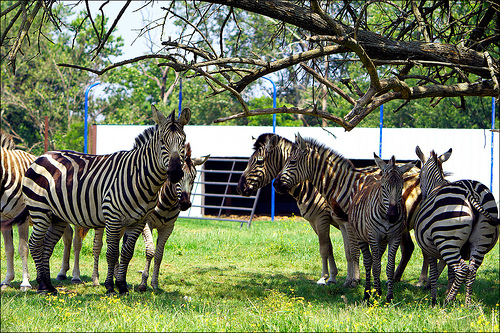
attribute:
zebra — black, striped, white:
[24, 114, 182, 292]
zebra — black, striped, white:
[415, 145, 498, 303]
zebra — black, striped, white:
[349, 156, 408, 306]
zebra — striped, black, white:
[273, 134, 348, 214]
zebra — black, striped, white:
[235, 132, 272, 196]